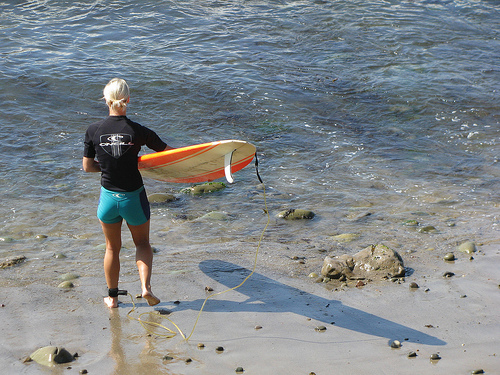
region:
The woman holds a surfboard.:
[59, 72, 266, 322]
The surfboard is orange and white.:
[122, 127, 272, 198]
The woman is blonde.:
[90, 72, 142, 120]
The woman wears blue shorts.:
[85, 181, 155, 237]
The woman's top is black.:
[70, 109, 175, 206]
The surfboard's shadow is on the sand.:
[124, 256, 461, 358]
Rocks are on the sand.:
[283, 222, 486, 295]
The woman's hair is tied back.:
[96, 82, 136, 119]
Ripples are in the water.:
[0, 16, 485, 130]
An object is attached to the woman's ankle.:
[92, 275, 137, 311]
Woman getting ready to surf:
[47, 52, 283, 322]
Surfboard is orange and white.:
[117, 135, 281, 200]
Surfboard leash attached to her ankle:
[105, 282, 134, 304]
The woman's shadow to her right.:
[150, 240, 447, 358]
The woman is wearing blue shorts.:
[77, 170, 161, 237]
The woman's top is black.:
[81, 102, 170, 199]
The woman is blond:
[96, 75, 143, 111]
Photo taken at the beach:
[15, 14, 492, 367]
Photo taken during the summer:
[14, 10, 490, 364]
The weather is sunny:
[7, 5, 490, 366]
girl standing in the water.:
[72, 62, 273, 312]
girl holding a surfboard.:
[125, 125, 271, 197]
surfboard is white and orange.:
[134, 135, 262, 195]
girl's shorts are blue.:
[91, 177, 156, 230]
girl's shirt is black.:
[74, 110, 164, 195]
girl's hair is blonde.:
[97, 72, 131, 113]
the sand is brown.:
[1, 233, 498, 371]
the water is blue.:
[2, 0, 498, 206]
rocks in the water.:
[143, 167, 333, 252]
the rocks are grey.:
[150, 167, 311, 229]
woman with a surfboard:
[47, 62, 304, 345]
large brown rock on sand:
[301, 223, 448, 311]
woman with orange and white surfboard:
[69, 58, 287, 322]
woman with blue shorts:
[65, 79, 195, 315]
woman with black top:
[58, 71, 190, 316]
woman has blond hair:
[76, 68, 187, 276]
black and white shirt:
[50, 72, 205, 328]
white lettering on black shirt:
[71, 95, 210, 214]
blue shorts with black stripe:
[58, 186, 218, 262]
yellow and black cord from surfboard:
[89, 155, 274, 357]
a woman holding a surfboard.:
[51, 69, 276, 313]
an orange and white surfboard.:
[133, 80, 284, 182]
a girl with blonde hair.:
[92, 77, 163, 139]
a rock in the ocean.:
[295, 222, 474, 373]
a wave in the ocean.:
[0, 41, 421, 132]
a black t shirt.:
[61, 105, 189, 191]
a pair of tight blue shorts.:
[79, 170, 164, 258]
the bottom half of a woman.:
[91, 183, 154, 331]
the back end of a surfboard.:
[189, 123, 267, 194]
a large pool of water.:
[226, 36, 392, 293]